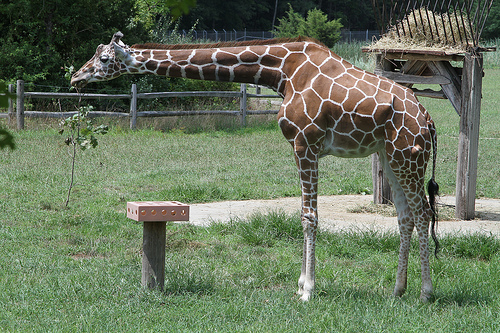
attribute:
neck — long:
[135, 38, 310, 95]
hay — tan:
[366, 6, 475, 70]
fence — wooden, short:
[0, 79, 283, 134]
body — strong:
[277, 52, 434, 158]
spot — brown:
[311, 71, 337, 103]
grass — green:
[1, 44, 500, 332]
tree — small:
[55, 61, 112, 210]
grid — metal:
[379, 0, 496, 53]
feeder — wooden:
[360, 1, 497, 223]